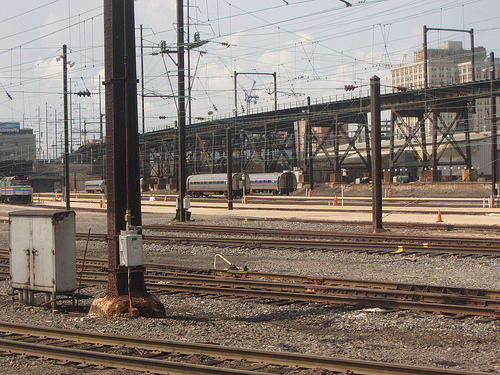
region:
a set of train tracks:
[0, 318, 465, 373]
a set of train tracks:
[1, 247, 498, 324]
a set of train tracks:
[70, 232, 498, 259]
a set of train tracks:
[140, 222, 498, 244]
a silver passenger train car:
[238, 168, 298, 195]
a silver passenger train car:
[186, 170, 237, 193]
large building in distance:
[388, 38, 496, 135]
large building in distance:
[0, 119, 37, 162]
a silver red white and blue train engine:
[2, 175, 32, 200]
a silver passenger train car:
[81, 180, 106, 193]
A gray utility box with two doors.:
[7, 208, 77, 306]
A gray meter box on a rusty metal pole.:
[117, 230, 142, 269]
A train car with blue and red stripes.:
[0, 175, 33, 202]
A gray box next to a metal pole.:
[8, 208, 78, 309]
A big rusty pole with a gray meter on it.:
[103, 0, 145, 294]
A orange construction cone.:
[436, 209, 443, 223]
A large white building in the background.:
[390, 44, 499, 133]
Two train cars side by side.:
[187, 170, 297, 192]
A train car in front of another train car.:
[183, 173, 250, 195]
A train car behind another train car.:
[247, 172, 297, 195]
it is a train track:
[16, 315, 203, 371]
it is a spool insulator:
[341, 75, 372, 95]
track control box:
[5, 200, 78, 311]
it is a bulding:
[390, 40, 495, 85]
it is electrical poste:
[170, 1, 205, 211]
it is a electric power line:
[260, 30, 395, 65]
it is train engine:
[0, 170, 35, 201]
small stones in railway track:
[34, 314, 261, 371]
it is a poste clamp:
[98, 74, 142, 91]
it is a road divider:
[436, 207, 444, 227]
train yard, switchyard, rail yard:
[0, 0, 499, 374]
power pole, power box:
[86, 0, 163, 322]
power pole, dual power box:
[153, 0, 210, 231]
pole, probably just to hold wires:
[351, 72, 399, 232]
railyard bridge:
[72, 64, 497, 205]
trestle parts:
[69, 106, 499, 199]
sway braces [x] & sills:
[141, 107, 476, 188]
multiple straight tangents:
[121, 100, 471, 205]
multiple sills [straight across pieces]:
[145, 136, 466, 166]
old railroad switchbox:
[3, 198, 81, 318]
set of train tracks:
[186, 212, 275, 255]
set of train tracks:
[175, 265, 320, 305]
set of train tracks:
[33, 317, 219, 363]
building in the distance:
[1, 105, 47, 170]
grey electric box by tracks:
[1, 197, 111, 327]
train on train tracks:
[175, 155, 265, 210]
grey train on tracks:
[175, 162, 311, 197]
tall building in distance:
[390, 36, 496, 106]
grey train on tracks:
[77, 171, 109, 191]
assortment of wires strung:
[0, 3, 125, 108]